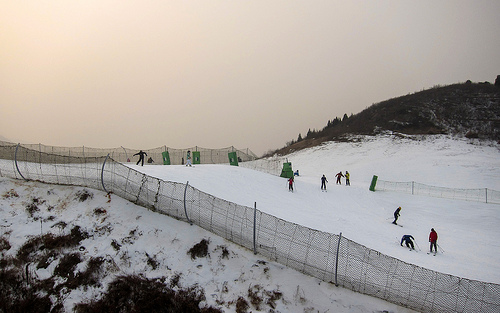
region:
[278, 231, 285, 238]
part of a fecne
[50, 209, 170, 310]
plants are coverd of snow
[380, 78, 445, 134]
plants are at the background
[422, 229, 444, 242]
jacket is red in color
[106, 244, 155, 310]
plants are black in color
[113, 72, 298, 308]
view was taken at sunset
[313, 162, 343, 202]
outfit is balck in color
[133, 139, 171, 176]
a man is skiing in the field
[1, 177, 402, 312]
Brown and white hill before the fence.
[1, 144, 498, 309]
The darkest net fence close to the camera.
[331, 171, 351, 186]
Two people past the fence standing together, one with arms out.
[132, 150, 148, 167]
Very dark person with their arms out.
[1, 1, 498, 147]
A grey sky.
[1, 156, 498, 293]
White snow between fences.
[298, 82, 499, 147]
A brown hill on top of the picture.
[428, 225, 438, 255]
Person down the furthest with red coat on.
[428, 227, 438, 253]
Red coat person standing down the hill.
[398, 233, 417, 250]
Blue coat person who is getting up at the bottom of the hill.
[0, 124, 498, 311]
snowy landscape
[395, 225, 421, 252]
skier falling down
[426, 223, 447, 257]
skier wearing red ski suit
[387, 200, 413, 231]
skier skiing downhill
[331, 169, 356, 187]
two people attempting to ski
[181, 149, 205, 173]
person walking in the snow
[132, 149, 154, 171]
person starting to ski down the hill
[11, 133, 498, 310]
snow surrounded by a fence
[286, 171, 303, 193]
child in red skiing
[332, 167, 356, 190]
couple helping each other to ski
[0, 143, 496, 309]
black fence enclosing some people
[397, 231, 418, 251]
person fallign over in the snow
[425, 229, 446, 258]
person wearing red coat and skiing gear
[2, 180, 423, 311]
snowy hill with visible vegetation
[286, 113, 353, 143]
distant pine trees on a hill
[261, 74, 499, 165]
hill towering above some snow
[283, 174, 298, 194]
person in red clothing with skiing gear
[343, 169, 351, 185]
person with yellow jacket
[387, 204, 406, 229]
person skiing to the right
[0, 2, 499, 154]
pink and grey sky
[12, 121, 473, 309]
snow on the ground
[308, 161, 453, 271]
a group of people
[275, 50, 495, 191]
hill on the side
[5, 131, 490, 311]
trim on the track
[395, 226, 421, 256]
a person is falling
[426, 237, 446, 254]
person holding ski poles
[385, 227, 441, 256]
the people are skiing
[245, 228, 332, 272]
fence in the snow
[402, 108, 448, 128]
trees on the mountain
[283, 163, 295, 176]
the sign is green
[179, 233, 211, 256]
rock on the snow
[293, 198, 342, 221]
the snow is smooth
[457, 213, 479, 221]
the snow is white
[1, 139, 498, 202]
a long fencing net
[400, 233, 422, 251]
a person skiing downhill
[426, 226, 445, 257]
a person skiing downhill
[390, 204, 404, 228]
a person skiing downhill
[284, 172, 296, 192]
a person skiing downhill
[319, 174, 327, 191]
a person skiing downhill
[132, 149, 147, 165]
a person skiing downhill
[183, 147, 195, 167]
a person skiing downhill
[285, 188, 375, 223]
snow on the ground